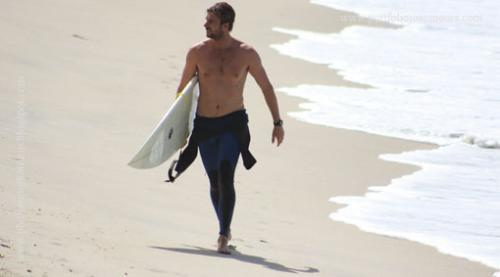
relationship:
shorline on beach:
[299, 2, 484, 274] [2, 1, 117, 276]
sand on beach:
[0, 256, 444, 276] [2, 1, 117, 276]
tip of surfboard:
[127, 158, 155, 170] [128, 68, 200, 171]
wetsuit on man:
[192, 110, 257, 237] [178, 3, 286, 255]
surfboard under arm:
[128, 68, 200, 171] [181, 46, 198, 88]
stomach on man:
[198, 93, 243, 120] [178, 3, 286, 255]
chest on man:
[200, 42, 246, 86] [178, 3, 286, 255]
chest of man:
[200, 42, 246, 86] [178, 3, 286, 255]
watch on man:
[274, 119, 283, 129] [178, 3, 286, 255]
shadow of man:
[155, 245, 320, 275] [178, 3, 286, 255]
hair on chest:
[219, 59, 225, 77] [200, 42, 246, 86]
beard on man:
[206, 28, 224, 40] [178, 3, 286, 255]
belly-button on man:
[216, 103, 221, 109] [178, 3, 286, 255]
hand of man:
[272, 123, 285, 145] [178, 3, 286, 255]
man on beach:
[178, 3, 286, 255] [2, 1, 117, 276]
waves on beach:
[439, 119, 500, 152] [2, 1, 117, 276]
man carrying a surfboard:
[178, 3, 286, 255] [128, 68, 200, 171]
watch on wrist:
[274, 119, 283, 129] [273, 112, 281, 122]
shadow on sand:
[155, 245, 320, 275] [0, 256, 444, 276]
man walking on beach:
[178, 3, 286, 255] [2, 1, 117, 276]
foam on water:
[449, 103, 500, 151] [445, 0, 499, 275]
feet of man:
[217, 234, 231, 254] [178, 3, 286, 255]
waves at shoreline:
[439, 119, 500, 152] [299, 2, 484, 274]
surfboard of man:
[128, 68, 200, 171] [178, 3, 286, 255]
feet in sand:
[217, 236, 230, 254] [0, 256, 444, 276]